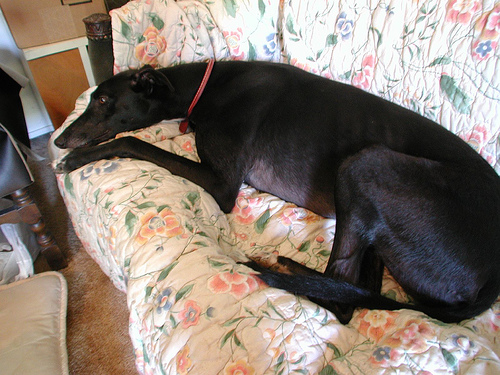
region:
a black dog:
[54, 59, 496, 323]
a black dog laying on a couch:
[47, 58, 496, 323]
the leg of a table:
[2, 135, 64, 270]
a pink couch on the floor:
[5, 280, 70, 372]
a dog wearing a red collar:
[52, 60, 228, 172]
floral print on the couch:
[143, 215, 267, 343]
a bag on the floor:
[3, 236, 48, 273]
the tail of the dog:
[268, 251, 460, 327]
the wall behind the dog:
[33, 45, 89, 105]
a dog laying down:
[53, 70, 250, 187]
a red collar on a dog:
[196, 53, 227, 112]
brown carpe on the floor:
[71, 272, 122, 374]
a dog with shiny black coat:
[76, 71, 474, 309]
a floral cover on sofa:
[121, 182, 271, 360]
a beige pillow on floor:
[4, 268, 69, 371]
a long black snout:
[51, 114, 103, 149]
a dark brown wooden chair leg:
[11, 192, 64, 263]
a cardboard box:
[3, 0, 103, 50]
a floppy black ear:
[131, 60, 185, 102]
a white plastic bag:
[1, 229, 31, 274]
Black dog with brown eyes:
[48, 58, 498, 327]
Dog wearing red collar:
[51, 51, 498, 323]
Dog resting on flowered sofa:
[49, 3, 499, 369]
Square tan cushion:
[4, 268, 72, 373]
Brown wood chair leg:
[4, 71, 69, 278]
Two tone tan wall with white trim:
[5, 2, 123, 139]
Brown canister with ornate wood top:
[83, 11, 120, 83]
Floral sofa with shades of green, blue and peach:
[44, 1, 499, 369]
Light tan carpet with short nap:
[4, 130, 143, 374]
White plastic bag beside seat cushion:
[1, 201, 72, 373]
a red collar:
[195, 65, 217, 86]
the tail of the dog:
[285, 267, 328, 297]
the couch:
[140, 255, 247, 361]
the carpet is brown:
[72, 309, 119, 343]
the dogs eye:
[94, 94, 111, 106]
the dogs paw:
[56, 154, 88, 167]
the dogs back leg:
[330, 217, 372, 283]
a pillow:
[7, 287, 67, 345]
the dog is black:
[83, 61, 403, 223]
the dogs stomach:
[270, 173, 312, 203]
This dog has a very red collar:
[193, 55, 216, 101]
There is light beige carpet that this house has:
[80, 293, 90, 317]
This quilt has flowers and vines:
[165, 258, 220, 319]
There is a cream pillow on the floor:
[5, 307, 38, 362]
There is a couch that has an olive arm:
[76, 10, 124, 66]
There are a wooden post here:
[13, 195, 59, 270]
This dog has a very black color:
[291, 95, 367, 177]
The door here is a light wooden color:
[56, 78, 68, 123]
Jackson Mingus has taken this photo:
[100, 102, 366, 358]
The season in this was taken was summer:
[69, 97, 378, 370]